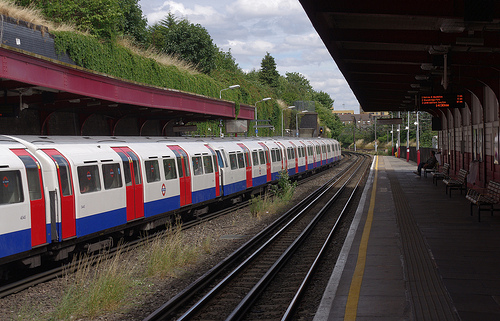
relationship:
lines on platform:
[313, 155, 381, 320] [311, 153, 499, 320]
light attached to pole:
[263, 96, 271, 103] [253, 95, 272, 139]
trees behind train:
[20, 0, 220, 74] [0, 133, 345, 272]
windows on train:
[76, 161, 124, 194] [0, 133, 345, 272]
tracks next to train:
[141, 149, 371, 320] [0, 133, 345, 272]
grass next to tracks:
[43, 245, 145, 320] [141, 149, 371, 320]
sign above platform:
[414, 91, 466, 110] [311, 153, 499, 320]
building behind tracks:
[339, 112, 372, 129] [141, 149, 371, 320]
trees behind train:
[245, 53, 338, 107] [0, 133, 345, 272]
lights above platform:
[398, 23, 463, 105] [311, 153, 499, 320]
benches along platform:
[419, 156, 498, 221] [311, 153, 499, 320]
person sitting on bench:
[411, 149, 437, 177] [422, 160, 440, 179]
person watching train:
[411, 149, 437, 177] [0, 133, 345, 272]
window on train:
[0, 167, 29, 207] [0, 133, 345, 272]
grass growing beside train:
[250, 176, 295, 221] [0, 133, 345, 272]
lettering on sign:
[421, 94, 448, 108] [414, 91, 466, 110]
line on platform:
[344, 140, 379, 320] [311, 153, 499, 320]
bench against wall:
[443, 166, 467, 195] [438, 83, 500, 189]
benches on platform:
[419, 156, 498, 221] [311, 153, 499, 320]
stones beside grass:
[5, 292, 48, 320] [43, 245, 145, 320]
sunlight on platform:
[371, 152, 418, 173] [311, 153, 499, 320]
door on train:
[110, 144, 146, 221] [0, 133, 345, 272]